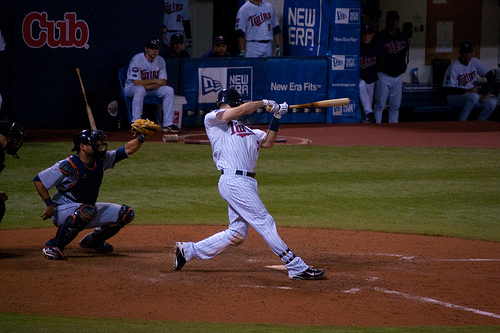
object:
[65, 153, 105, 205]
vest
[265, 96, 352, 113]
bat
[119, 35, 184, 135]
players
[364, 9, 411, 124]
players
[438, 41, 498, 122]
players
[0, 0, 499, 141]
dug out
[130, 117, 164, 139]
mitt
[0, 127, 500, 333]
ground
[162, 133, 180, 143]
can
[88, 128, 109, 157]
mask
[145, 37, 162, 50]
man cap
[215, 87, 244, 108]
hat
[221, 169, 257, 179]
belt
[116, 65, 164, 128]
chair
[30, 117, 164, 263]
catcher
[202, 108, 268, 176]
shirt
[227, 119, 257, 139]
name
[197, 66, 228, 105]
white symbol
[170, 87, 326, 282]
batter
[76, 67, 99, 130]
bat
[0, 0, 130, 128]
wall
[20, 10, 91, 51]
print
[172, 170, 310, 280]
pants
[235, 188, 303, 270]
leg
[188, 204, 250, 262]
leg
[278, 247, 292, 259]
bands